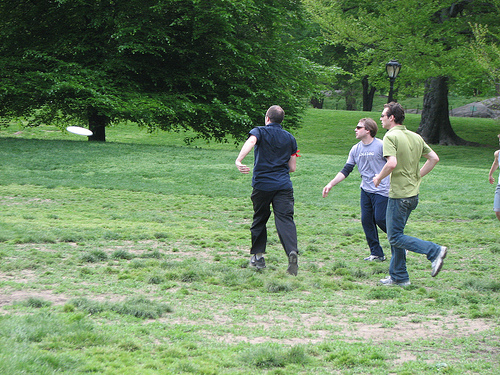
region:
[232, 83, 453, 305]
three people running in a field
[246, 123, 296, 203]
a navy blue shirt on a man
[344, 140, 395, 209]
a grey shirt with white writing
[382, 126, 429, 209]
a light green shirt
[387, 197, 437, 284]
denim pants on a man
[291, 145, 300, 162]
a red tie on a man's arm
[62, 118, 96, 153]
a white frisbee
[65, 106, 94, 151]
a frisbee flying through the air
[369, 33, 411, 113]
a lamp post in a park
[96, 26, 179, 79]
green leaves on a tree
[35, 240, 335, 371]
dirt and grass cover the ground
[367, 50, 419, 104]
a light post in the background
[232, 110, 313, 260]
a man running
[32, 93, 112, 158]
a frisbee in the air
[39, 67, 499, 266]
every one running towards the frisbee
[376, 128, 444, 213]
a lime green shirt on the man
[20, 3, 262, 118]
a large tree in the background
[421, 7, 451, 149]
a tree trunk in the background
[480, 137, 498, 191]
a person on the right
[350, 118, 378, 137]
the man is wearing sunglasses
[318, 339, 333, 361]
part of a field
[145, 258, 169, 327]
part of the grass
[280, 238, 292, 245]
part of a trouser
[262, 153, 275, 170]
back of a man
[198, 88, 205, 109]
part of a bush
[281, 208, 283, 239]
back of a leg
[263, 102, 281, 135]
head of a man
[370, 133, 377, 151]
part of a shirt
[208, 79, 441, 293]
People playing frisbee in the park.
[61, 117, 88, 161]
A white frisbee in the air.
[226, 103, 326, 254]
The man is running toward frisbee.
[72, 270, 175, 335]
Patches in the grass.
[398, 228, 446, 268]
One leg off the ground.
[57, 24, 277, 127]
A big tree in the park.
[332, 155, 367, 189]
The person is wearing a elbow pad.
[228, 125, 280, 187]
The man is wearing blue shirt.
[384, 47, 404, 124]
A lamp post in the park.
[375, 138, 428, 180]
The man is wearing a green shirt.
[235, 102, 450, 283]
men chasing a Frisbee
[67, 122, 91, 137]
white Frisbee in the air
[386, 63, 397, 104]
black lamp post in the distance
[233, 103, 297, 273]
man with dark shirt and pants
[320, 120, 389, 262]
man with gray shirt and sun glasses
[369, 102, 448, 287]
man with light green shirt and sunglasses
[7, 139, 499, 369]
open field with patchy grass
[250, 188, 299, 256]
black jogging pants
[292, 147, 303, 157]
red ribbon on man's right arm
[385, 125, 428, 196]
green polo shirt